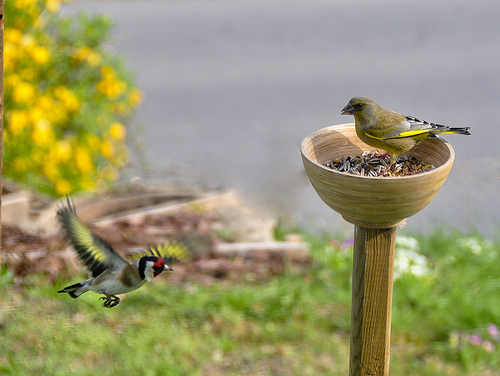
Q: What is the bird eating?
A: Bird seed.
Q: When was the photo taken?
A: Daytime.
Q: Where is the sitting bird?
A: Bird feeder.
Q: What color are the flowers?
A: Yellow.